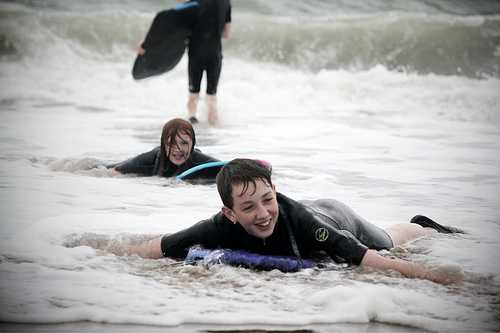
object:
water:
[262, 66, 475, 165]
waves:
[245, 8, 494, 81]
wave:
[0, 10, 128, 67]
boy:
[107, 158, 469, 282]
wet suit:
[159, 198, 395, 274]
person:
[136, 0, 232, 126]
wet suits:
[184, 2, 231, 95]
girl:
[89, 117, 233, 182]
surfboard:
[173, 159, 272, 183]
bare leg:
[207, 93, 217, 126]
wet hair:
[156, 118, 196, 177]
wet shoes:
[410, 215, 466, 235]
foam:
[239, 65, 494, 160]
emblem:
[315, 227, 330, 242]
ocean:
[2, 33, 116, 203]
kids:
[101, 0, 464, 287]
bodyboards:
[131, 3, 197, 80]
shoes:
[190, 116, 199, 125]